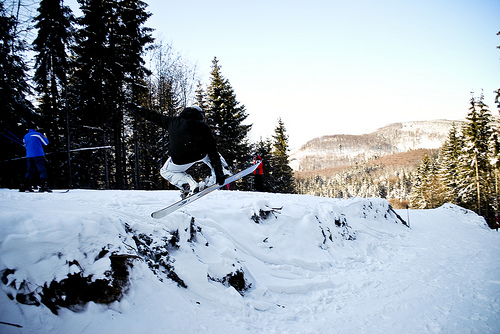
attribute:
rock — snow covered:
[10, 212, 232, 324]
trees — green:
[468, 94, 498, 216]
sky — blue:
[1, 1, 496, 168]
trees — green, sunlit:
[35, 0, 140, 135]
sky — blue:
[161, 3, 498, 125]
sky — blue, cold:
[233, 5, 488, 82]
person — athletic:
[114, 90, 281, 232]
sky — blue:
[316, 22, 383, 76]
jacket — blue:
[23, 130, 44, 157]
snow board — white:
[151, 157, 261, 217]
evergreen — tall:
[267, 117, 297, 192]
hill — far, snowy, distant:
[279, 121, 493, 229]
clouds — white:
[184, 7, 209, 36]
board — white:
[147, 176, 239, 218]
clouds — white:
[248, 25, 363, 100]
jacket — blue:
[22, 127, 48, 161]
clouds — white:
[253, 82, 427, 131]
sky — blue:
[6, 3, 499, 151]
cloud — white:
[171, 4, 456, 131]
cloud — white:
[183, 8, 473, 146]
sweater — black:
[135, 101, 230, 180]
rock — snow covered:
[340, 196, 408, 231]